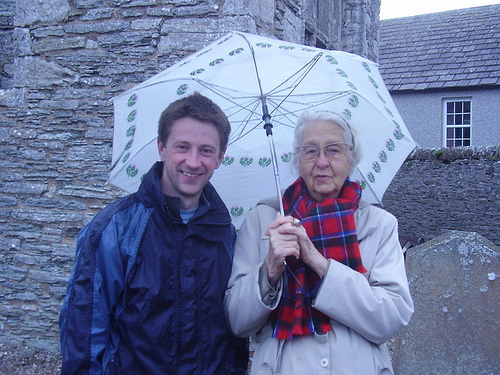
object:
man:
[58, 90, 251, 375]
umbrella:
[104, 30, 418, 233]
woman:
[230, 104, 413, 373]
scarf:
[268, 176, 367, 340]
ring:
[293, 218, 302, 226]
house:
[376, 2, 499, 154]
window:
[440, 96, 473, 147]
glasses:
[297, 141, 348, 162]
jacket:
[221, 189, 416, 374]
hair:
[293, 108, 362, 172]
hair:
[155, 90, 231, 154]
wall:
[380, 227, 499, 374]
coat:
[58, 162, 252, 374]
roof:
[376, 3, 499, 93]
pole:
[260, 98, 285, 226]